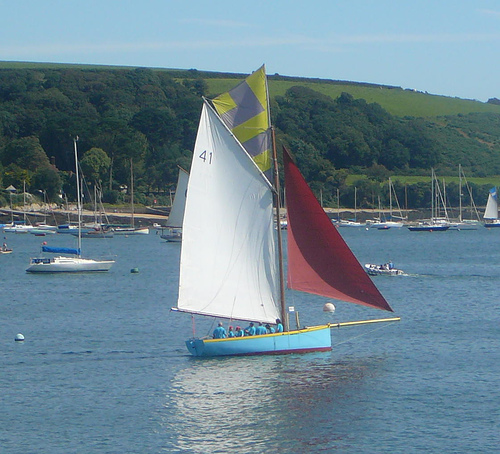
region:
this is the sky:
[294, 2, 486, 67]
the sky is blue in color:
[361, 11, 448, 46]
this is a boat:
[195, 201, 318, 355]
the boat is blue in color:
[246, 338, 273, 348]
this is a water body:
[339, 380, 454, 451]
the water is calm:
[362, 347, 493, 427]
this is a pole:
[266, 132, 290, 292]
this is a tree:
[87, 143, 112, 182]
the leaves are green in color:
[83, 151, 102, 161]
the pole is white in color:
[66, 139, 86, 213]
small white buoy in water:
[7, 330, 34, 350]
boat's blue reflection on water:
[252, 350, 356, 375]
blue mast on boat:
[41, 239, 96, 255]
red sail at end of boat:
[283, 149, 416, 338]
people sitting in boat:
[201, 311, 305, 339]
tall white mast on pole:
[169, 93, 286, 328]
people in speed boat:
[360, 257, 412, 285]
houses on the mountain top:
[366, 73, 437, 99]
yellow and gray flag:
[200, 70, 303, 185]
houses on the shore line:
[27, 163, 148, 228]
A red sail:
[279, 136, 409, 319]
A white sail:
[176, 89, 281, 328]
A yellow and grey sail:
[201, 63, 281, 174]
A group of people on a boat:
[199, 308, 289, 339]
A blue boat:
[181, 331, 345, 358]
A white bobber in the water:
[11, 326, 36, 347]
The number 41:
[197, 143, 219, 165]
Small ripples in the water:
[254, 383, 416, 443]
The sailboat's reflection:
[170, 362, 350, 452]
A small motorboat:
[363, 249, 410, 284]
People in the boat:
[208, 320, 303, 336]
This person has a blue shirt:
[212, 318, 228, 338]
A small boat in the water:
[368, 258, 405, 275]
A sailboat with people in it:
[168, 65, 403, 356]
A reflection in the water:
[173, 358, 290, 453]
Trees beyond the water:
[3, 93, 413, 188]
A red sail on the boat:
[281, 148, 390, 311]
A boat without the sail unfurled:
[26, 134, 115, 271]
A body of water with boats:
[2, 229, 499, 450]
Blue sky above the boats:
[1, 0, 498, 102]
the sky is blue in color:
[331, 19, 415, 58]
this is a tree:
[336, 110, 376, 160]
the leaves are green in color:
[346, 127, 378, 149]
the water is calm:
[48, 295, 121, 406]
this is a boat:
[34, 250, 112, 275]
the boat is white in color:
[63, 259, 90, 266]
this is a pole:
[73, 122, 82, 236]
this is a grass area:
[383, 86, 420, 104]